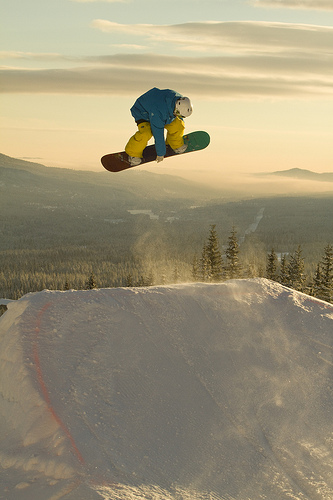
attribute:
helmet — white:
[176, 92, 192, 116]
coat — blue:
[135, 87, 168, 120]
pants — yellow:
[133, 120, 182, 161]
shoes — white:
[129, 142, 188, 165]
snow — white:
[32, 275, 302, 454]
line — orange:
[27, 297, 82, 491]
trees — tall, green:
[185, 220, 328, 321]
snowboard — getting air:
[92, 124, 224, 185]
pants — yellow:
[124, 122, 189, 158]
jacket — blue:
[129, 90, 170, 122]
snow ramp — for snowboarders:
[8, 285, 320, 495]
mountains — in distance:
[4, 166, 326, 263]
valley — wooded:
[6, 225, 323, 300]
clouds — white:
[104, 13, 311, 76]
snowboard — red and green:
[97, 128, 214, 176]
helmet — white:
[168, 84, 198, 121]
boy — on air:
[97, 79, 222, 175]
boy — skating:
[86, 82, 214, 187]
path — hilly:
[50, 282, 278, 495]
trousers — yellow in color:
[124, 127, 151, 154]